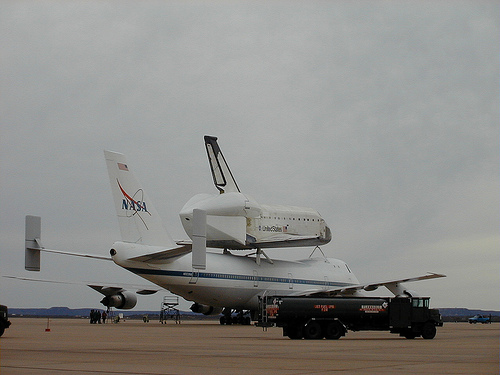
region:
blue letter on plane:
[119, 198, 130, 210]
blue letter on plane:
[128, 198, 137, 212]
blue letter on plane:
[136, 196, 142, 212]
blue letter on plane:
[140, 197, 146, 214]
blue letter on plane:
[261, 223, 266, 233]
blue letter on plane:
[271, 224, 276, 231]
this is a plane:
[94, 123, 456, 337]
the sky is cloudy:
[279, 76, 383, 193]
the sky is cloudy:
[228, 34, 298, 141]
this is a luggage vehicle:
[265, 273, 456, 353]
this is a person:
[91, 305, 104, 328]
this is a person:
[100, 303, 115, 330]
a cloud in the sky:
[36, 141, 48, 159]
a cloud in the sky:
[310, 143, 327, 168]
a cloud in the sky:
[77, 206, 100, 224]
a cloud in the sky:
[363, 210, 379, 220]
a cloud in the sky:
[426, 143, 442, 161]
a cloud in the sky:
[6, 145, 8, 150]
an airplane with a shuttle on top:
[20, 130, 450, 315]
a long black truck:
[275, 286, 440, 341]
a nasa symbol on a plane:
[115, 177, 152, 232]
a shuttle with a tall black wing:
[177, 133, 331, 261]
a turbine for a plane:
[98, 288, 140, 313]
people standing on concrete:
[85, 306, 110, 327]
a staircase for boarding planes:
[156, 293, 183, 325]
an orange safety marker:
[42, 313, 54, 335]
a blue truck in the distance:
[466, 311, 492, 327]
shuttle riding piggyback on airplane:
[30, 126, 447, 323]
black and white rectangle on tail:
[201, 131, 243, 198]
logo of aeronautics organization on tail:
[109, 172, 159, 230]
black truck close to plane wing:
[265, 272, 447, 343]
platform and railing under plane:
[157, 292, 182, 326]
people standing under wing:
[80, 303, 111, 326]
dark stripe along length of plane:
[129, 262, 362, 288]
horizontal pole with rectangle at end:
[21, 211, 111, 271]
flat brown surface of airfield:
[2, 315, 493, 369]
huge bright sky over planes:
[5, 7, 497, 309]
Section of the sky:
[399, 163, 463, 248]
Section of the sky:
[275, 80, 377, 168]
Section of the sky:
[58, 58, 154, 155]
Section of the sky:
[53, 151, 205, 272]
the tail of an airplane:
[105, 158, 192, 270]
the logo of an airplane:
[104, 196, 154, 224]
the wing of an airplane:
[347, 265, 451, 306]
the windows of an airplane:
[237, 278, 282, 290]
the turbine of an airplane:
[95, 288, 152, 319]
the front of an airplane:
[305, 246, 383, 291]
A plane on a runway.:
[20, 131, 472, 345]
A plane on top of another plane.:
[182, 128, 338, 264]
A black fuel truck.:
[271, 292, 453, 347]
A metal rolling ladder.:
[154, 290, 184, 330]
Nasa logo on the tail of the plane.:
[111, 170, 158, 240]